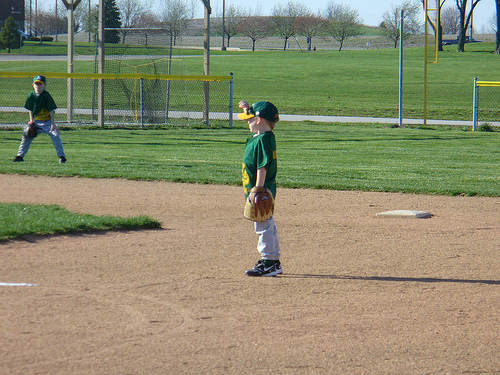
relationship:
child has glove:
[238, 100, 280, 277] [243, 187, 275, 223]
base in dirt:
[374, 207, 433, 219] [0, 173, 500, 375]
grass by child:
[0, 204, 161, 243] [238, 100, 280, 277]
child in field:
[238, 100, 280, 277] [1, 37, 500, 374]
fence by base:
[0, 72, 234, 128] [374, 207, 433, 219]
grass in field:
[1, 41, 499, 199] [1, 37, 500, 374]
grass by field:
[1, 41, 499, 199] [1, 37, 500, 374]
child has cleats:
[238, 100, 280, 277] [246, 259, 282, 277]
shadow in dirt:
[273, 273, 500, 284] [0, 173, 500, 375]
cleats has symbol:
[246, 259, 282, 277] [263, 262, 275, 271]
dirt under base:
[0, 173, 500, 375] [374, 207, 433, 219]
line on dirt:
[0, 281, 36, 286] [0, 173, 500, 375]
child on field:
[238, 100, 280, 277] [1, 37, 500, 374]